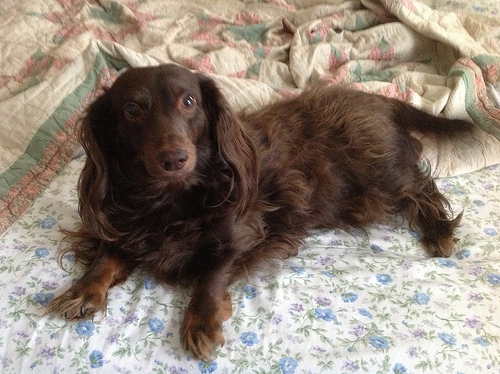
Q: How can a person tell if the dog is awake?
A: Eyes are open.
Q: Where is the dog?
A: On a bed.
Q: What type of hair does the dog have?
A: Long.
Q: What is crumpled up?
A: Quilt.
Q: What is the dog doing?
A: Lying.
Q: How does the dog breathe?
A: Nose.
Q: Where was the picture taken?
A: Bedroom.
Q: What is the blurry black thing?
A: Tail.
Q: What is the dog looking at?
A: Camera.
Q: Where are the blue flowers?
A: On the blanket.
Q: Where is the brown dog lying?
A: On the blankets.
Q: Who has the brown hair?
A: The dog.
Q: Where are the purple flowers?
A: On the blanket.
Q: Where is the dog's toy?
A: It is not pictured.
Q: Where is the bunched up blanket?
A: On the bed, behind the dog.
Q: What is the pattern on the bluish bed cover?
A: Floral.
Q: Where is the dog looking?
A: At camera.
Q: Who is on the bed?
A: Brown dog.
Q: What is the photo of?
A: Dog on the bed.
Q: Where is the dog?
A: Bed.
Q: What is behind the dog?
A: Blanket.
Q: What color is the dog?
A: Brown.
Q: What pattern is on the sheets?
A: Flowers.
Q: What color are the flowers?
A: Blue.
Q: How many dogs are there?
A: 1.